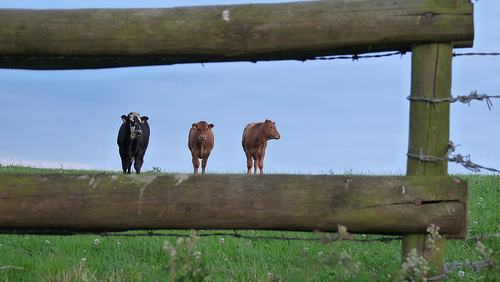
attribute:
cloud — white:
[21, 154, 93, 174]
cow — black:
[114, 111, 169, 178]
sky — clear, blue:
[38, 73, 385, 110]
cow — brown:
[237, 112, 284, 174]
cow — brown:
[182, 119, 219, 176]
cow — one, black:
[110, 107, 155, 174]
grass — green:
[0, 166, 499, 280]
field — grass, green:
[2, 165, 498, 272]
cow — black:
[113, 111, 149, 178]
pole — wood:
[397, 43, 457, 191]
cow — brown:
[189, 120, 214, 173]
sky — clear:
[0, 5, 500, 177]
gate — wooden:
[7, 3, 480, 264]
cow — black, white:
[115, 112, 148, 174]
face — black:
[126, 114, 143, 136]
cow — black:
[114, 108, 150, 171]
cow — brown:
[243, 116, 283, 172]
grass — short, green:
[2, 236, 398, 281]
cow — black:
[93, 81, 343, 183]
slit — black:
[390, 190, 460, 209]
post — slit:
[5, 165, 468, 234]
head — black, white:
[122, 110, 150, 140]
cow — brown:
[238, 118, 284, 177]